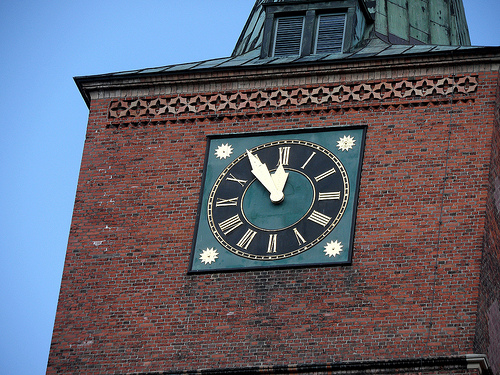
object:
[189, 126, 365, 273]
clock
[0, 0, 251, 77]
sky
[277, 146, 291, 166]
numeral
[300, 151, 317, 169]
numeral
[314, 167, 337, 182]
numeral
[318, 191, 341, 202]
numeral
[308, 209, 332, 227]
numeral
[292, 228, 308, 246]
five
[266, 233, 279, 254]
numeral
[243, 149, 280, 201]
hand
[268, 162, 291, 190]
hand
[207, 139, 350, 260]
face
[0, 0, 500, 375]
background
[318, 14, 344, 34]
slats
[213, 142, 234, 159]
flower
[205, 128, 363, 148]
top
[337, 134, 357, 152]
shape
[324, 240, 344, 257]
shape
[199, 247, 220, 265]
shape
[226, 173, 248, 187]
numerals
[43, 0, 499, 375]
building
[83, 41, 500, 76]
roof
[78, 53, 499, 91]
ledge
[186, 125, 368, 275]
border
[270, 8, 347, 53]
shutters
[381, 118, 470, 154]
bricks